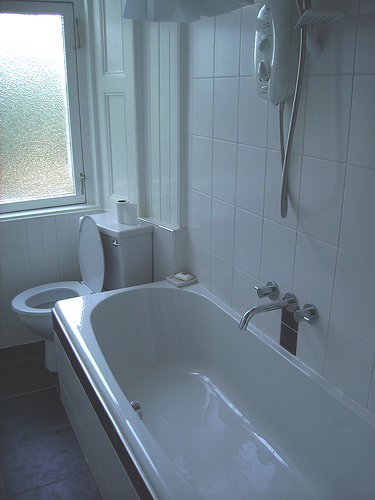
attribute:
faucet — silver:
[236, 278, 319, 325]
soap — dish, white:
[166, 264, 203, 275]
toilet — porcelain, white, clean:
[17, 249, 116, 329]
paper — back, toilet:
[108, 191, 140, 216]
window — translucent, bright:
[10, 52, 75, 191]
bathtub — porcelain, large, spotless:
[125, 319, 290, 466]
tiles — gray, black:
[23, 408, 97, 496]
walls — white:
[177, 83, 264, 200]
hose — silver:
[272, 118, 315, 192]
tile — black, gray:
[13, 385, 52, 458]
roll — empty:
[107, 183, 158, 231]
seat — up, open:
[56, 206, 119, 269]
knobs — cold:
[243, 269, 312, 321]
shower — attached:
[235, 34, 311, 122]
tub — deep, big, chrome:
[239, 275, 297, 330]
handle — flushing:
[97, 235, 131, 249]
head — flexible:
[251, 24, 353, 129]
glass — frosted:
[24, 64, 96, 154]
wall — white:
[174, 61, 270, 188]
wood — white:
[92, 79, 166, 164]